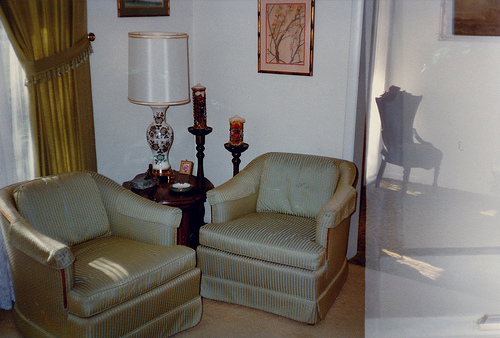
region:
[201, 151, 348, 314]
chair in the room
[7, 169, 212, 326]
chair next to window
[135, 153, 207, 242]
table with items on it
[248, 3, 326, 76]
image on the wall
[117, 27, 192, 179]
lamp on the table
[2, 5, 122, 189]
curtain to the window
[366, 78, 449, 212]
chair in room outside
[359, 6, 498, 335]
clear curtain in the room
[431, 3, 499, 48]
image on wall in other room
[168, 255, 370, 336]
carpet in the room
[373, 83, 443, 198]
Vintage arm chair in the corner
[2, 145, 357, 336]
Pair of older upholstered chairs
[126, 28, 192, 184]
Large lamp with white shade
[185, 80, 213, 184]
Candle on a pillar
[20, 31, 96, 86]
Gold drape tieback with frills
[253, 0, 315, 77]
Pink art in gold frame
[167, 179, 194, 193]
Empty ashtray on side table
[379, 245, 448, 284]
Sun shines through to the floor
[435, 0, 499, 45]
White frame on the far wall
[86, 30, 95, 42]
Decorative gold fastener for drapes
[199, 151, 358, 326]
Chair covered in fabric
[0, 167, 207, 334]
Chair covered in fabric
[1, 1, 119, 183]
Drape hanging on side of window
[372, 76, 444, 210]
Chair in the background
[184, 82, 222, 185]
Candle stick holder near the wall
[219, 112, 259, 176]
Candle stick holder near the wall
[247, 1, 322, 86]
Picture hanging on the wall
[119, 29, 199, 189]
Lamp on the table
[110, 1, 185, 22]
Picture over the lamp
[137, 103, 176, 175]
Floral pattern on the lamp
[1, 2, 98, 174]
long gold drapes over a white sheer curtain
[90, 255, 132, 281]
sunlight on a tan upholstered chair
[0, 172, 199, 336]
one of two tan upholstered chairs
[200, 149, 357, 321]
one of two tan upholstered chairs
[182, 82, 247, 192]
two fancy candles on fancy wood stands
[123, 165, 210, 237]
dark brown wood table between two tan upholstered chairs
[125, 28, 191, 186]
decorative lamp between two tan upholstered chairs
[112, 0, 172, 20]
framed art between two tan upholstered chairs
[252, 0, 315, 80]
framed art on a white wall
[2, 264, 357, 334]
brown carpeting under two tan upholstered chairs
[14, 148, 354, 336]
grey seats in room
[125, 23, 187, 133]
white lampshade on table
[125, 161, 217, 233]
table is round and brown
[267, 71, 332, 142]
white wall behind chairs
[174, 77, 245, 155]
two candles on stands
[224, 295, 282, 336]
carpet is light brown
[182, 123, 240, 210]
candles on brown stands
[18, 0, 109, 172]
golden curtains behind chair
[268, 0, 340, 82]
pink and brown picture frame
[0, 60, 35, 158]
white sheer on window